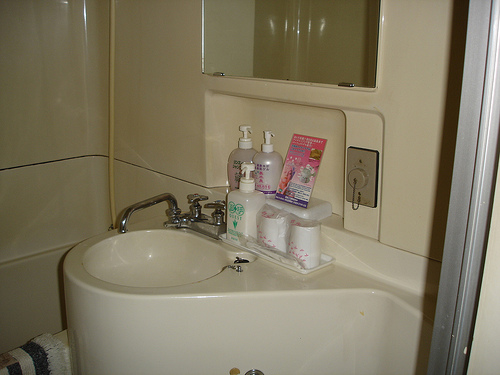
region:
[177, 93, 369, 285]
items next to sink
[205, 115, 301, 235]
bottles near the sink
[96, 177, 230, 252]
faucet of the sink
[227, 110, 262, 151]
top of the bottle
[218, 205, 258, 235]
writing on the bottle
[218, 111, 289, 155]
two tops of the bottle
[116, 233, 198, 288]
inner part of sink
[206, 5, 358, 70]
mirror above the sink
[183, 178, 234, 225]
handles of the faucet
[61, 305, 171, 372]
bottom of the sink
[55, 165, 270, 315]
Sink in a bathroom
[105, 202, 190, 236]
Faucet in a bathoom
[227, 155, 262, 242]
Lotion in a bathroom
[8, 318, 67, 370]
Towel in a bathroom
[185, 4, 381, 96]
Mirror in a bathroom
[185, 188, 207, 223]
Metal handle on a sink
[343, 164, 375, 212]
Cover on an electric outlet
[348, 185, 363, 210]
Chain on a safety cover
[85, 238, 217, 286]
Bowl of a sink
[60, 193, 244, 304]
A small sink.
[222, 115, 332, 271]
Lotions and soap for the sink.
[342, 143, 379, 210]
A socket that is covered.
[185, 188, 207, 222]
The hot water tap.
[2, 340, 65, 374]
A towel over the tub.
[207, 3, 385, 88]
A bathroom mirror.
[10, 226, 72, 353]
An empty tub.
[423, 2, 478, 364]
The doorway to the bathroom.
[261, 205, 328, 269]
Cups sit on the sink.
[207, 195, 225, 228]
The cold water tap.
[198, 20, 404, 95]
mirror on wall above sink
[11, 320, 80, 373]
a blue and white towel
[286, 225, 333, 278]
plastic cups on sink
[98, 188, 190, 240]
silver faucet of sink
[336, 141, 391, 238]
a socket on the wall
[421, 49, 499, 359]
part of the door frame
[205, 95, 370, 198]
a cut out above the sink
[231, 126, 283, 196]
two bottles of hair supplies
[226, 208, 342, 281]
a tray with bathroom accessories on it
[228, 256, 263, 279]
drain plug for the sink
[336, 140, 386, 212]
Plug on the wall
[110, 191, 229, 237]
Silver faucet behindd the sink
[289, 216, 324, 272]
Cups on the counter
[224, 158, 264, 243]
Bottle on the counter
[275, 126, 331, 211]
Paper on the sink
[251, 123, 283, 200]
Bottle on the counter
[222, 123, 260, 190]
Bottle on the counter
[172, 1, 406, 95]
Mirror over the sink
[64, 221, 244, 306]
Circular sink under the faucet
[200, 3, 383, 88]
Clean mirror on the wall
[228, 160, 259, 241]
square plastic bottle with a white pump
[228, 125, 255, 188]
clear plastic bottle with a white pump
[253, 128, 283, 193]
clear plastic bottle with a white pump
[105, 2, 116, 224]
skinny off white colored hose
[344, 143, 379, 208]
silver covered wall outlet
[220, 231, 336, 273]
white tray with toiletries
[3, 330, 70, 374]
white bath mat with blue stripes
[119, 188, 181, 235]
silver faucet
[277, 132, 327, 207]
shower cap in a pink package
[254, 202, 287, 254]
cup in plastic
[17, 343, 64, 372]
blue and white towel hanging on the side of the tub